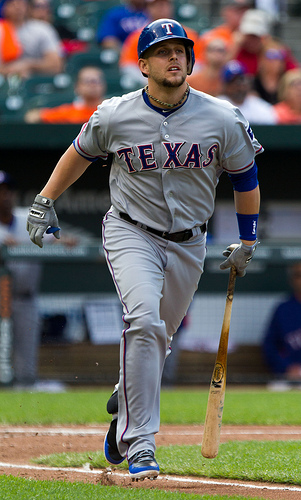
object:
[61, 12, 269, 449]
baseball player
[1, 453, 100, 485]
line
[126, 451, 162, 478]
shoe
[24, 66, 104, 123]
person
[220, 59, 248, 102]
man/blue hat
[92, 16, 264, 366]
man/blue hat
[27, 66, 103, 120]
man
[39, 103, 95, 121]
shirt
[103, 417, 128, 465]
shoe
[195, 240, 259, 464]
bat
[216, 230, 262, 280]
hand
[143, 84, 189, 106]
necklace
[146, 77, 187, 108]
neck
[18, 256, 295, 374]
wall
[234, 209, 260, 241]
sweat band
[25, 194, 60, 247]
glove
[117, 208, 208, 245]
belt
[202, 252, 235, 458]
wooden bat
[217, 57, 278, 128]
person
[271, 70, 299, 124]
person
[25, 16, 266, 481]
person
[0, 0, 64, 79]
person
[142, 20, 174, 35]
helmet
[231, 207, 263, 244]
arm band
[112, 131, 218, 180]
texas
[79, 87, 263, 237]
jersey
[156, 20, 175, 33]
letter t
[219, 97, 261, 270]
arm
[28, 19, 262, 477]
man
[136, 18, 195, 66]
hat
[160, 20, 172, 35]
t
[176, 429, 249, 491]
ground